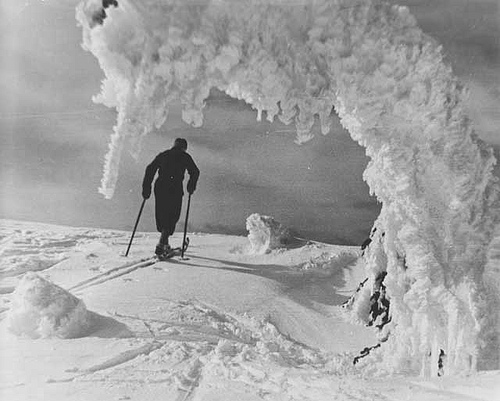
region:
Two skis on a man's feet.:
[140, 237, 192, 267]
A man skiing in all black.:
[142, 136, 199, 258]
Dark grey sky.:
[1, 1, 384, 245]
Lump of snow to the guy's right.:
[245, 214, 294, 254]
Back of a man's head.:
[170, 137, 189, 152]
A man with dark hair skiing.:
[142, 137, 199, 255]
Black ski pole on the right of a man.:
[179, 192, 192, 259]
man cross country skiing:
[119, 137, 205, 265]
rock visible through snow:
[355, 235, 397, 363]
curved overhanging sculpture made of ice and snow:
[78, 0, 498, 377]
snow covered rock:
[245, 215, 294, 252]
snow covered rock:
[9, 277, 84, 342]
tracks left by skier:
[65, 258, 162, 295]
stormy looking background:
[5, 0, 497, 233]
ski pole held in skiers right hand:
[179, 188, 191, 258]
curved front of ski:
[176, 234, 192, 255]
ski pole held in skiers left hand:
[124, 193, 148, 258]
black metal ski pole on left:
[111, 196, 150, 263]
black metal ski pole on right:
[176, 185, 196, 262]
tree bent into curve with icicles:
[61, 3, 498, 386]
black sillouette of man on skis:
[118, 136, 207, 265]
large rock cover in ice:
[4, 266, 100, 343]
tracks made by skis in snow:
[64, 248, 160, 296]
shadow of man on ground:
[169, 243, 352, 311]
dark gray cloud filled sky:
[4, 3, 499, 252]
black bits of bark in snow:
[351, 224, 453, 382]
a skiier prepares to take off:
[125, 130, 200, 268]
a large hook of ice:
[76, 0, 497, 377]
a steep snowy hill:
[3, 200, 355, 275]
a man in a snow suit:
[117, 131, 208, 273]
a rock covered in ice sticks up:
[237, 197, 314, 259]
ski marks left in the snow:
[95, 274, 322, 394]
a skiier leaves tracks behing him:
[83, 131, 218, 292]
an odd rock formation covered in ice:
[73, 3, 498, 378]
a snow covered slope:
[6, 211, 498, 399]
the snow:
[193, 268, 248, 310]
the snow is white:
[129, 265, 181, 313]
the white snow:
[94, 325, 175, 376]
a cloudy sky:
[28, 78, 75, 138]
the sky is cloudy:
[18, 75, 66, 147]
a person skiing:
[140, 140, 200, 265]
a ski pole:
[183, 197, 193, 242]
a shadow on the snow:
[251, 260, 293, 281]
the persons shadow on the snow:
[188, 243, 297, 288]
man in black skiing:
[122, 132, 201, 268]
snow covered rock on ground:
[239, 212, 300, 259]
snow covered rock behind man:
[4, 268, 96, 344]